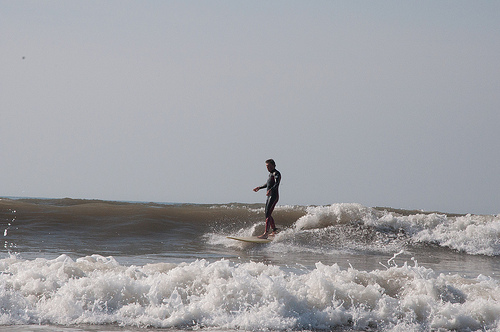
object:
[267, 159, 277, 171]
head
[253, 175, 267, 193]
arm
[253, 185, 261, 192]
hand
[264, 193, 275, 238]
legs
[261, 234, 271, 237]
feet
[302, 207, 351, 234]
crest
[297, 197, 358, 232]
wave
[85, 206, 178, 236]
gray ocean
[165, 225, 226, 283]
water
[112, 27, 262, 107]
gray sky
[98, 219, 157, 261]
ocean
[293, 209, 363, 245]
breaking wave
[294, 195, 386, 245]
shoreline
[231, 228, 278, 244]
long ivory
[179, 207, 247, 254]
wave break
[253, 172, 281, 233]
wet suit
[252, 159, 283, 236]
male surfer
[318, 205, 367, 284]
waves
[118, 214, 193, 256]
white and brown